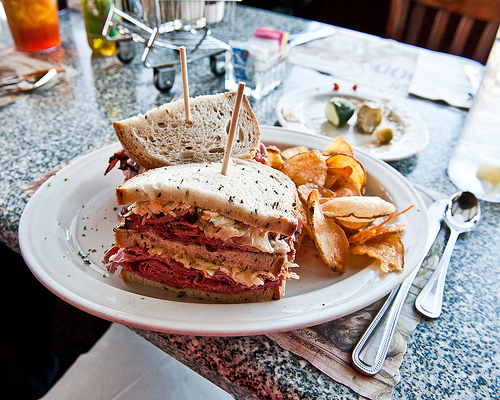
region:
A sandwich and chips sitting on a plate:
[15, 84, 431, 336]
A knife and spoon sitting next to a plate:
[345, 185, 482, 372]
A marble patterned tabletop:
[8, 17, 498, 396]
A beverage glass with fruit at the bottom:
[438, 20, 499, 207]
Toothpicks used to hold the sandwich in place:
[161, 38, 251, 280]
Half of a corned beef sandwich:
[111, 155, 301, 301]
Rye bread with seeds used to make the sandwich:
[113, 85, 304, 237]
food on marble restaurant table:
[3, 1, 497, 398]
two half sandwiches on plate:
[19, 85, 429, 334]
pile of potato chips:
[265, 137, 407, 269]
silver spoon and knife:
[352, 189, 479, 376]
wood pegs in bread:
[177, 46, 244, 177]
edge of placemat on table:
[269, 183, 456, 398]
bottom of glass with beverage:
[4, 1, 59, 55]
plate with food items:
[277, 84, 430, 159]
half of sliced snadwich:
[117, 158, 302, 302]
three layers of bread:
[114, 187, 292, 300]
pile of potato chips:
[278, 138, 413, 274]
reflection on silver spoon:
[417, 189, 480, 317]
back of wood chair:
[387, 1, 498, 48]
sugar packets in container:
[227, 28, 289, 96]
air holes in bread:
[122, 87, 257, 164]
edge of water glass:
[449, 34, 499, 204]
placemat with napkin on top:
[292, 21, 478, 107]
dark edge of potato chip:
[324, 198, 396, 223]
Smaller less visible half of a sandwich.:
[111, 89, 269, 179]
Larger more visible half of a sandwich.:
[101, 155, 303, 302]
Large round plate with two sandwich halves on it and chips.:
[16, 124, 430, 339]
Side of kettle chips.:
[263, 137, 412, 278]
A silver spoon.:
[414, 191, 481, 318]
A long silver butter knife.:
[348, 196, 450, 378]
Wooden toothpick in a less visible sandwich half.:
[178, 44, 191, 122]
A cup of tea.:
[2, 2, 62, 52]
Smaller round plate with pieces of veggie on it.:
[277, 81, 430, 164]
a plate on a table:
[17, 63, 409, 335]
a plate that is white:
[59, 117, 436, 352]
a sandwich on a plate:
[49, 70, 389, 372]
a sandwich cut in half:
[91, 78, 348, 323]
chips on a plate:
[259, 129, 381, 297]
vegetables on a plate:
[287, 34, 432, 180]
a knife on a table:
[375, 172, 436, 399]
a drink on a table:
[3, 1, 63, 66]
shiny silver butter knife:
[352, 198, 449, 375]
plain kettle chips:
[267, 135, 414, 272]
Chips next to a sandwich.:
[285, 132, 410, 268]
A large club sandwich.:
[107, 164, 302, 307]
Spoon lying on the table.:
[413, 187, 485, 323]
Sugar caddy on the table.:
[221, 24, 299, 101]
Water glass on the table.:
[450, 7, 497, 207]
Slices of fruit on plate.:
[294, 77, 414, 146]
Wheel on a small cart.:
[149, 62, 178, 92]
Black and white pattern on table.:
[410, 315, 499, 395]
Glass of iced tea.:
[1, 0, 63, 56]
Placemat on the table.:
[293, 22, 481, 85]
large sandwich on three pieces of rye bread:
[112, 86, 304, 308]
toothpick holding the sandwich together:
[218, 77, 247, 174]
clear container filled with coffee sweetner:
[221, 25, 293, 99]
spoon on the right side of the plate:
[411, 191, 483, 319]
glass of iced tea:
[0, 3, 67, 52]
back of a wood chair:
[378, 5, 498, 62]